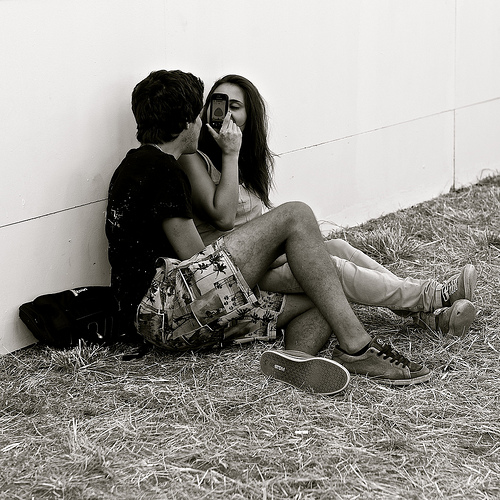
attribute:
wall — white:
[2, 2, 500, 325]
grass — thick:
[2, 173, 499, 494]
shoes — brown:
[254, 338, 430, 408]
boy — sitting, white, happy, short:
[86, 58, 428, 420]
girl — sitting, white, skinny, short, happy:
[198, 71, 477, 342]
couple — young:
[104, 64, 489, 399]